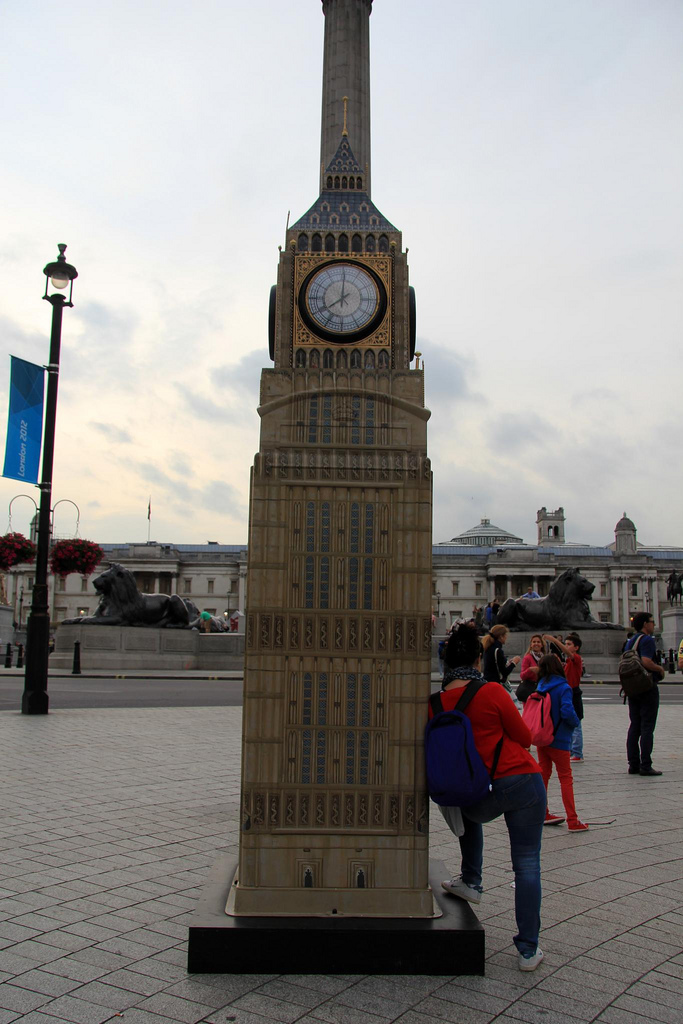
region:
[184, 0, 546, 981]
woman leaning on big ben replica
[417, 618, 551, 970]
girl carrying blue backpack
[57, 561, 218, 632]
a statue of a lion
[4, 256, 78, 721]
a black light post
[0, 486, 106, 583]
planters with red flowers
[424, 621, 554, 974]
girl wearing red shirt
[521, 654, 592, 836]
girl wearing red pants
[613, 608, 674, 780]
man carrying a backpack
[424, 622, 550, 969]
girl wearing a scarf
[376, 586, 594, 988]
the girl is leaning on the base of the clock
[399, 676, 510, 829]
the girl is wearing a bookbag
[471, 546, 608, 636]
statue of a lion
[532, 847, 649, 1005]
the ground is made of brick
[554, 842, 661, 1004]
the ground is light grey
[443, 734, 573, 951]
the girl is wearing jeans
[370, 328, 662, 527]
the sky is overcast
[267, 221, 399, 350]
the clock is surrounded by gold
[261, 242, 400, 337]
the face of the clock is white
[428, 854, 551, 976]
the girl is wearing sneakers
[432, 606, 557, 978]
a person wearing blue jeans and carrying a backpack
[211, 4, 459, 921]
statue of leaning clock tower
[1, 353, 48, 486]
blue banner with white writing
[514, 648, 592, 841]
person wearing red leggings and blue jacket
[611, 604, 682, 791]
person wearing blue top and black pants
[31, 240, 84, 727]
an older black streetlight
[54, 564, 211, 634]
a large bronze statue of a lion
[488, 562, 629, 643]
large bronze statue of a lion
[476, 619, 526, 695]
woman wearing ponytail and black top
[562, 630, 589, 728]
dark-haired person in red top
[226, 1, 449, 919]
clock on tower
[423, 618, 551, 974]
woman wearing red sweater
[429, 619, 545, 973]
woman wearing blue backpack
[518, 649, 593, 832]
girl wearing blue jacket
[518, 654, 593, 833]
girl is wearing a red backpack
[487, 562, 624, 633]
lion statue is dark gray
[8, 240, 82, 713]
blue banner on black metal pole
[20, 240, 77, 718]
streetlight on black metal pole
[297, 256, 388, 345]
clock has a white face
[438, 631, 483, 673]
person has a head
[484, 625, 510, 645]
person has a head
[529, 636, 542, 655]
person has a head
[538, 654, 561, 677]
person has a head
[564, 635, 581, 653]
person has a head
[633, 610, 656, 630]
person has a head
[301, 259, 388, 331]
clock on the tower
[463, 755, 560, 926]
woman wearing blue jeans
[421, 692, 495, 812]
woman wearing a blue bag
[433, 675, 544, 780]
woman wearing a red sweater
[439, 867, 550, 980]
woman wearing white shoes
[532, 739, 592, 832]
woman wearing red pants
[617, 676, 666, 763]
man wearing black pants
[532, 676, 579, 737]
woman wearing blue jacket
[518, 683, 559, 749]
girl wearing a pink backpack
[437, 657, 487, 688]
woman wearing a scarf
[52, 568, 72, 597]
a window on a building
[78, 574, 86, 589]
a window on a building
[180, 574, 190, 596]
a window on a building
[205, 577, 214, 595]
a window on a building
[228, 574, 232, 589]
a window on a building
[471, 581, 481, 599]
a window on a building